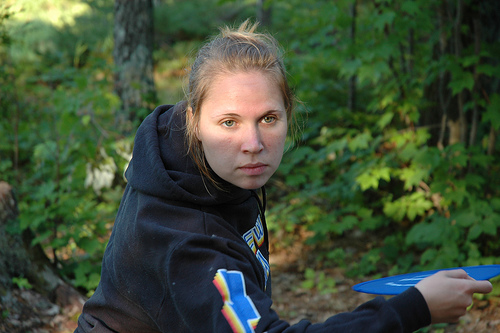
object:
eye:
[220, 119, 239, 127]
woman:
[76, 23, 490, 333]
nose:
[241, 119, 264, 154]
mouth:
[233, 161, 271, 174]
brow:
[213, 111, 246, 119]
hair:
[183, 17, 311, 199]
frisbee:
[351, 263, 499, 296]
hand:
[412, 268, 492, 325]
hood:
[123, 103, 245, 203]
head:
[183, 29, 291, 191]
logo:
[212, 269, 261, 333]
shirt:
[74, 101, 432, 333]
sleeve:
[166, 235, 430, 333]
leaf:
[353, 173, 380, 193]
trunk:
[111, 0, 152, 129]